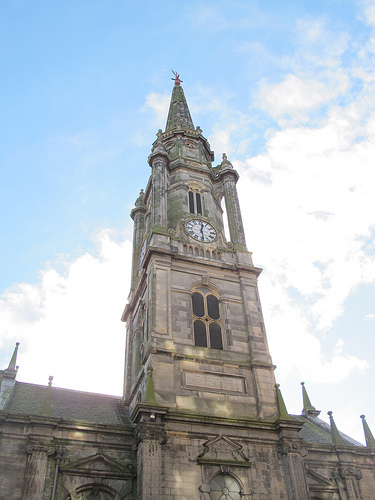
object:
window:
[191, 283, 225, 349]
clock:
[185, 218, 217, 242]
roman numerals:
[209, 235, 214, 238]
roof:
[157, 83, 196, 132]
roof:
[3, 380, 128, 424]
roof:
[290, 414, 358, 445]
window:
[189, 189, 202, 216]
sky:
[0, 0, 372, 445]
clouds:
[238, 105, 375, 338]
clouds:
[10, 231, 123, 381]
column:
[215, 153, 249, 251]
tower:
[116, 66, 283, 418]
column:
[146, 128, 171, 232]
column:
[128, 185, 145, 280]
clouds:
[320, 345, 359, 385]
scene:
[0, 0, 375, 500]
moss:
[144, 370, 158, 405]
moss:
[274, 384, 291, 420]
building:
[1, 64, 375, 500]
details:
[275, 429, 307, 457]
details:
[165, 140, 175, 149]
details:
[170, 245, 178, 252]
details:
[137, 420, 167, 443]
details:
[198, 434, 247, 459]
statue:
[170, 69, 183, 86]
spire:
[301, 382, 322, 418]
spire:
[327, 409, 345, 445]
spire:
[359, 416, 375, 446]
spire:
[6, 344, 20, 373]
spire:
[38, 372, 60, 416]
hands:
[200, 224, 204, 231]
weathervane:
[170, 69, 185, 83]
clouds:
[21, 288, 42, 310]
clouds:
[257, 61, 322, 126]